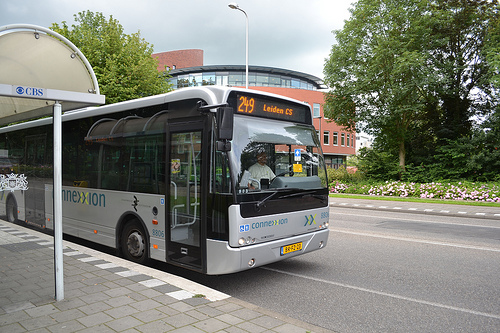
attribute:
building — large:
[299, 66, 361, 171]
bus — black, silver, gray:
[2, 81, 337, 281]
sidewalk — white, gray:
[0, 225, 244, 323]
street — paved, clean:
[321, 204, 485, 330]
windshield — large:
[225, 111, 332, 197]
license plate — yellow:
[282, 242, 304, 253]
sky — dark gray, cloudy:
[129, 3, 326, 57]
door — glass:
[166, 125, 206, 268]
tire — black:
[118, 212, 148, 265]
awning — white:
[0, 21, 111, 109]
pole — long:
[227, 3, 255, 89]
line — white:
[269, 264, 494, 322]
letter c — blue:
[25, 86, 31, 97]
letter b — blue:
[30, 87, 40, 98]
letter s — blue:
[38, 89, 46, 96]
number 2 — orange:
[236, 92, 246, 112]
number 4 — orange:
[242, 94, 250, 112]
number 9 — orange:
[248, 96, 256, 114]